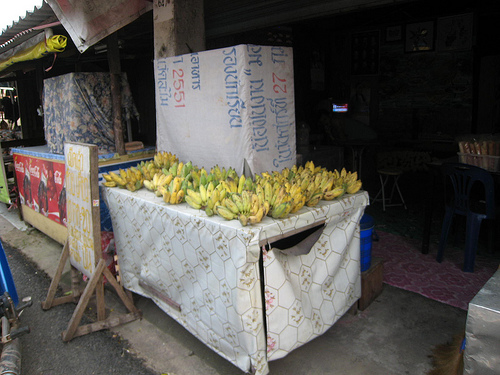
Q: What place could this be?
A: It is a market.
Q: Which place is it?
A: It is a market.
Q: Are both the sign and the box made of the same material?
A: Yes, both the sign and the box are made of wood.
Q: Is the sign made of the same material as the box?
A: Yes, both the sign and the box are made of wood.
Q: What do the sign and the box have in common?
A: The material, both the sign and the box are wooden.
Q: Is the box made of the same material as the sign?
A: Yes, both the box and the sign are made of wood.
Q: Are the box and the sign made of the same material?
A: Yes, both the box and the sign are made of wood.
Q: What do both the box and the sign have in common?
A: The material, both the box and the sign are wooden.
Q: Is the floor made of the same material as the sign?
A: No, the floor is made of cement and the sign is made of wood.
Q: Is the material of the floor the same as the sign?
A: No, the floor is made of cement and the sign is made of wood.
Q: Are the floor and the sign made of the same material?
A: No, the floor is made of cement and the sign is made of wood.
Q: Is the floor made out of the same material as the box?
A: No, the floor is made of cement and the box is made of wood.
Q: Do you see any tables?
A: Yes, there is a table.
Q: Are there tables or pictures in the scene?
A: Yes, there is a table.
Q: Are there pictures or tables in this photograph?
A: Yes, there is a table.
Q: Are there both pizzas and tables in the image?
A: No, there is a table but no pizzas.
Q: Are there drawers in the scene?
A: No, there are no drawers.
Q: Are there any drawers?
A: No, there are no drawers.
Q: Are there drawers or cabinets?
A: No, there are no drawers or cabinets.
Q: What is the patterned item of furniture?
A: The piece of furniture is a table.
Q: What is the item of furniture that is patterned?
A: The piece of furniture is a table.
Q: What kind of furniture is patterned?
A: The furniture is a table.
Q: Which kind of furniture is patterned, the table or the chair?
A: The table is patterned.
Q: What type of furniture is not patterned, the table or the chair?
A: The chair is not patterned.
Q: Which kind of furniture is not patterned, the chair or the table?
A: The chair is not patterned.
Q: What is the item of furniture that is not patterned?
A: The piece of furniture is a chair.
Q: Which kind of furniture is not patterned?
A: The furniture is a chair.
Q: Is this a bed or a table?
A: This is a table.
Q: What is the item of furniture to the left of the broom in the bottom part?
A: The piece of furniture is a table.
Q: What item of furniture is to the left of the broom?
A: The piece of furniture is a table.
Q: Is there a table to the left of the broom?
A: Yes, there is a table to the left of the broom.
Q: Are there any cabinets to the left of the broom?
A: No, there is a table to the left of the broom.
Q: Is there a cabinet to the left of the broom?
A: No, there is a table to the left of the broom.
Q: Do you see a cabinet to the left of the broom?
A: No, there is a table to the left of the broom.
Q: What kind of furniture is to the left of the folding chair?
A: The piece of furniture is a table.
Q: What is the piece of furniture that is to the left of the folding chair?
A: The piece of furniture is a table.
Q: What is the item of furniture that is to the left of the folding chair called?
A: The piece of furniture is a table.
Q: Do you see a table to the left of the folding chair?
A: Yes, there is a table to the left of the folding chair.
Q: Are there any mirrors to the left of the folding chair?
A: No, there is a table to the left of the folding chair.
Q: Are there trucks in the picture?
A: No, there are no trucks.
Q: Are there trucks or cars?
A: No, there are no trucks or cars.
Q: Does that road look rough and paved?
A: Yes, the road is rough and paved.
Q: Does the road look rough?
A: Yes, the road is rough.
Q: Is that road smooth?
A: No, the road is rough.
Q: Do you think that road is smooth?
A: No, the road is rough.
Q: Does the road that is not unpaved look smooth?
A: No, the road is rough.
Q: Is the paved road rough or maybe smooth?
A: The road is rough.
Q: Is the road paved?
A: Yes, the road is paved.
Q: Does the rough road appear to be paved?
A: Yes, the road is paved.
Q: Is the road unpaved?
A: No, the road is paved.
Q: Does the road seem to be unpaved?
A: No, the road is paved.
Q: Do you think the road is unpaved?
A: No, the road is paved.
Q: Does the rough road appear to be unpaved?
A: No, the road is paved.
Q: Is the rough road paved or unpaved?
A: The road is paved.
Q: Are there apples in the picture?
A: No, there are no apples.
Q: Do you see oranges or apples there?
A: No, there are no apples or oranges.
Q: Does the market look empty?
A: Yes, the market is empty.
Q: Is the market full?
A: No, the market is empty.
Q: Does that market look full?
A: No, the market is empty.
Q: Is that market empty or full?
A: The market is empty.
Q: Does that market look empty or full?
A: The market is empty.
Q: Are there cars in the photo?
A: No, there are no cars.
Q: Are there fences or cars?
A: No, there are no cars or fences.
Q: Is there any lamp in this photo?
A: No, there are no lamps.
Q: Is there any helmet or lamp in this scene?
A: No, there are no lamps or helmets.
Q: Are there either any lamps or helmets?
A: No, there are no lamps or helmets.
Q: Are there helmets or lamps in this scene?
A: No, there are no lamps or helmets.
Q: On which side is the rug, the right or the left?
A: The rug is on the right of the image.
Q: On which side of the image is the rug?
A: The rug is on the right of the image.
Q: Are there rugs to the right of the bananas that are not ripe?
A: Yes, there is a rug to the right of the bananas.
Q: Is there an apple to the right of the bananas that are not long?
A: No, there is a rug to the right of the bananas.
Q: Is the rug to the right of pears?
A: No, the rug is to the right of the bananas.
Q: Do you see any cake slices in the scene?
A: No, there are no cake slices.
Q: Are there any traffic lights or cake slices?
A: No, there are no cake slices or traffic lights.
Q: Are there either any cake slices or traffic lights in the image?
A: No, there are no cake slices or traffic lights.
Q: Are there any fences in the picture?
A: No, there are no fences.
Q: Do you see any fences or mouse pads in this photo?
A: No, there are no fences or mouse pads.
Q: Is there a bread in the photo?
A: Yes, there is a bread.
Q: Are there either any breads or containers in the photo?
A: Yes, there is a bread.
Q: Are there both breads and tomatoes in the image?
A: No, there is a bread but no tomatoes.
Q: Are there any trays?
A: No, there are no trays.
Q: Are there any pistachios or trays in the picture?
A: No, there are no trays or pistachios.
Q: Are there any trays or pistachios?
A: No, there are no trays or pistachios.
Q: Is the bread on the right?
A: Yes, the bread is on the right of the image.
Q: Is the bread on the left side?
A: No, the bread is on the right of the image.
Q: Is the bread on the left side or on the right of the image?
A: The bread is on the right of the image.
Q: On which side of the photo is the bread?
A: The bread is on the right of the image.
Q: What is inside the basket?
A: The bread is inside the basket.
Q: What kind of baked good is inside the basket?
A: The food is a bread.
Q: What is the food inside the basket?
A: The food is a bread.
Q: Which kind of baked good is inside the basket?
A: The food is a bread.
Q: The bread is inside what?
A: The bread is inside the basket.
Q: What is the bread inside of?
A: The bread is inside the basket.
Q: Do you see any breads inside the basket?
A: Yes, there is a bread inside the basket.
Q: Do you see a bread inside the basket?
A: Yes, there is a bread inside the basket.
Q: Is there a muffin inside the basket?
A: No, there is a bread inside the basket.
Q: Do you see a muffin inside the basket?
A: No, there is a bread inside the basket.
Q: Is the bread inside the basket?
A: Yes, the bread is inside the basket.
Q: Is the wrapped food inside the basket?
A: Yes, the bread is inside the basket.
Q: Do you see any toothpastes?
A: No, there are no toothpastes.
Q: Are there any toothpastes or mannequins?
A: No, there are no toothpastes or mannequins.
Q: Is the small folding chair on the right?
A: Yes, the folding chair is on the right of the image.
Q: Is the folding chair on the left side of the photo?
A: No, the folding chair is on the right of the image.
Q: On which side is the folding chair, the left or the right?
A: The folding chair is on the right of the image.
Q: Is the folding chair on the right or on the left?
A: The folding chair is on the right of the image.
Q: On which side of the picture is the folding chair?
A: The folding chair is on the right of the image.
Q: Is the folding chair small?
A: Yes, the folding chair is small.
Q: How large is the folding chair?
A: The folding chair is small.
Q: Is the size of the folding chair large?
A: No, the folding chair is small.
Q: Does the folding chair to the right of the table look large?
A: No, the folding chair is small.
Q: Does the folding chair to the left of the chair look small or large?
A: The folding chair is small.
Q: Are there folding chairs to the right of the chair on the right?
A: No, the folding chair is to the left of the chair.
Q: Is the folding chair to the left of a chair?
A: Yes, the folding chair is to the left of a chair.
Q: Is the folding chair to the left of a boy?
A: No, the folding chair is to the left of a chair.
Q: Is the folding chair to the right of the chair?
A: No, the folding chair is to the left of the chair.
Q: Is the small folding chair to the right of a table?
A: Yes, the folding chair is to the right of a table.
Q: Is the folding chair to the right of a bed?
A: No, the folding chair is to the right of a table.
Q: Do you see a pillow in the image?
A: No, there are no pillows.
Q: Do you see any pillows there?
A: No, there are no pillows.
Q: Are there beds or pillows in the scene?
A: No, there are no pillows or beds.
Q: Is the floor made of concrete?
A: Yes, the floor is made of concrete.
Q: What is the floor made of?
A: The floor is made of concrete.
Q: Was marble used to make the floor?
A: No, the floor is made of cement.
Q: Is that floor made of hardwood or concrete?
A: The floor is made of concrete.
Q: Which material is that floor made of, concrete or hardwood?
A: The floor is made of concrete.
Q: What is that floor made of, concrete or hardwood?
A: The floor is made of concrete.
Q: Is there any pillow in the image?
A: No, there are no pillows.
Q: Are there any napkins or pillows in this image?
A: No, there are no pillows or napkins.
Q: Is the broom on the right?
A: Yes, the broom is on the right of the image.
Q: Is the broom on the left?
A: No, the broom is on the right of the image.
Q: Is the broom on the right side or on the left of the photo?
A: The broom is on the right of the image.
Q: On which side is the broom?
A: The broom is on the right of the image.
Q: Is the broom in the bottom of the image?
A: Yes, the broom is in the bottom of the image.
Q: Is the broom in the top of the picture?
A: No, the broom is in the bottom of the image.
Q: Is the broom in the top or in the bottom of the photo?
A: The broom is in the bottom of the image.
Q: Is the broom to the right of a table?
A: Yes, the broom is to the right of a table.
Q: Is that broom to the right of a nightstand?
A: No, the broom is to the right of a table.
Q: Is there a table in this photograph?
A: Yes, there is a table.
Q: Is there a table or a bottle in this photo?
A: Yes, there is a table.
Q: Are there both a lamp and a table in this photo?
A: No, there is a table but no lamps.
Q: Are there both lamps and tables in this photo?
A: No, there is a table but no lamps.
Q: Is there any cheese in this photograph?
A: No, there is no cheese.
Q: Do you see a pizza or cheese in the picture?
A: No, there are no cheese or pizzas.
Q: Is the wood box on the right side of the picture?
A: Yes, the box is on the right of the image.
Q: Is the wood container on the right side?
A: Yes, the box is on the right of the image.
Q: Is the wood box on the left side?
A: No, the box is on the right of the image.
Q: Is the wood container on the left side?
A: No, the box is on the right of the image.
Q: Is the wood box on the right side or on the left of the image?
A: The box is on the right of the image.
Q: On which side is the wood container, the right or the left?
A: The box is on the right of the image.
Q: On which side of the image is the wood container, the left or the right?
A: The box is on the right of the image.